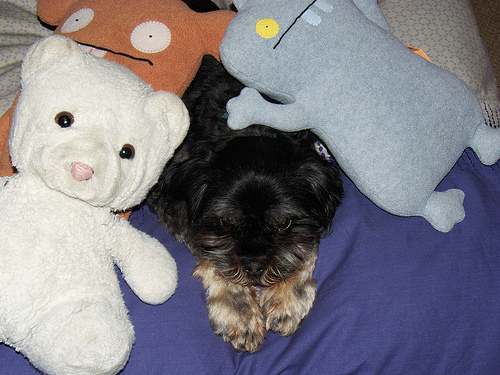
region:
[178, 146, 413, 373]
the dog is black and brown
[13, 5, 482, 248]
3 stuffed animals are on the bed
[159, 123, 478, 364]
the dog is on the bed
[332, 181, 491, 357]
the bed is blue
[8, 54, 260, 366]
the teddy bear is white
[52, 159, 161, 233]
the teddy bear's nose is pink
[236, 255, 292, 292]
the dog's nose is black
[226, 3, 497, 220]
the stuffed animal is grey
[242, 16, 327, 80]
the stuffed animals eyes are yellow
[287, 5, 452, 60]
the stuffed animal's teeth are white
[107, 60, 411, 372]
black dog on bed with blue blanket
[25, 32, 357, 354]
white teddy by dog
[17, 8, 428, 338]
three teddy bears on top of dog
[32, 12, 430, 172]
two teddy bears behind white teddy bear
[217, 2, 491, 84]
white pillow behind teddy bears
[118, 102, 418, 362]
black dog sleeping on bed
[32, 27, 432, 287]
dog sleeping on bed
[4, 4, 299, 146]
pillows on bed behind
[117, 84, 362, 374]
only one dog on bed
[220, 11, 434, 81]
teddy bear with yellow eye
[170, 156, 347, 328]
angry small puppy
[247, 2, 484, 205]
stuffed toy from nickelodeon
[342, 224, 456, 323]
bed that dog is on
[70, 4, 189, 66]
stuffed doll resembling cartoon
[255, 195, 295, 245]
dogs left eye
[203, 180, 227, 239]
right eye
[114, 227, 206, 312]
left arm of stuffed bear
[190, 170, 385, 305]
angry small yorkie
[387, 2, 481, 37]
pillow in background of photo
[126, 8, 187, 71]
left eye of orange doll behind dog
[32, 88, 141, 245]
white stuffed animal on the bed.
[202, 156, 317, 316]
dog on the bed.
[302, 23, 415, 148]
gray stuffed animal on the bed.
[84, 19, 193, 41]
orange stuffed animal on the bed.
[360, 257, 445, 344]
blue comforter on the bed.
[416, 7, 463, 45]
pillow underneath stuffed animals.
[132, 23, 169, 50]
white eye on stuffed animal.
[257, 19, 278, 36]
yellow eye on stuffed animal.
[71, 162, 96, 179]
pink nose on stuffed animal.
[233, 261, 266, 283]
black nose on dog.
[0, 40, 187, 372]
White stuffed bear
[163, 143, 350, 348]
Black and brown puppy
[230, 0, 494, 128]
Grey stuffed tory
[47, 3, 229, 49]
Eyes on a stuffed toy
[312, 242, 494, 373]
A purpler comforter on bed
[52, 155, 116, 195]
Pink nose on white stuffed bear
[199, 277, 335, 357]
Paws of a brown puppy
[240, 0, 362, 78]
Face of a grey stuffed toy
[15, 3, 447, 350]
Puppy covered in stuffed toys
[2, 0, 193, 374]
Two stuffed toys